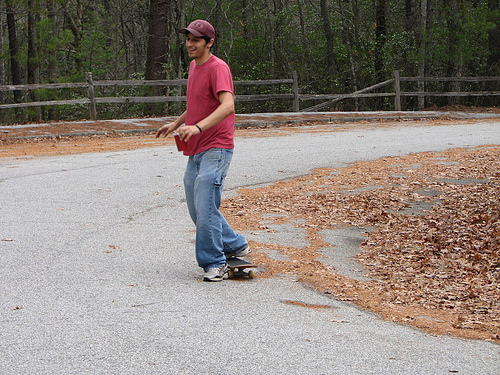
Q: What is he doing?
A: Skating.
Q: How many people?
A: 1.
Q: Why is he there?
A: To skate.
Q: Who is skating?
A: The guy.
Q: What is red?
A: His shirt.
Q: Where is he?
A: On the street.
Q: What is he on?
A: The street.